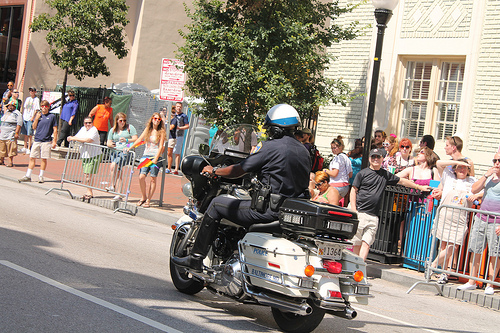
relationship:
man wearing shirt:
[86, 96, 113, 149] [93, 104, 112, 132]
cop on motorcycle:
[169, 103, 311, 272] [162, 117, 369, 329]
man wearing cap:
[341, 147, 433, 289] [370, 149, 384, 156]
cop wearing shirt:
[169, 103, 311, 272] [332, 150, 409, 214]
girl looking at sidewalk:
[320, 133, 356, 209] [1, 142, 498, 306]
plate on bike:
[314, 242, 345, 259] [175, 154, 361, 323]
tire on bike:
[168, 227, 206, 295] [168, 120, 371, 331]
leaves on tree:
[179, 3, 365, 108] [181, 0, 367, 151]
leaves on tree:
[79, 38, 84, 41] [169, 1, 373, 187]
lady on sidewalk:
[432, 160, 471, 279] [367, 259, 498, 308]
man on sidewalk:
[341, 147, 431, 280] [1, 142, 498, 306]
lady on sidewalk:
[432, 160, 471, 279] [1, 142, 498, 306]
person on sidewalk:
[471, 151, 496, 296] [1, 142, 498, 306]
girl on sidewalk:
[121, 112, 167, 208] [1, 142, 498, 306]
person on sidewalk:
[157, 90, 190, 175] [1, 142, 498, 306]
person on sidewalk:
[388, 134, 414, 171] [1, 142, 498, 306]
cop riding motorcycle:
[96, 78, 338, 242] [176, 145, 417, 312]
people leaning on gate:
[64, 100, 218, 213] [68, 144, 135, 201]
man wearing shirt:
[86, 96, 113, 149] [95, 105, 110, 128]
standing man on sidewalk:
[18, 98, 56, 193] [2, 144, 229, 222]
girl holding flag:
[97, 82, 182, 238] [136, 143, 178, 195]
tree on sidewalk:
[181, 0, 367, 151] [21, 135, 188, 223]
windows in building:
[411, 51, 495, 139] [313, 1, 483, 177]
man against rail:
[341, 147, 431, 280] [368, 175, 484, 286]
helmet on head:
[260, 104, 310, 140] [255, 99, 307, 147]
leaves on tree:
[207, 16, 269, 63] [176, 2, 341, 134]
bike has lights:
[170, 144, 368, 333] [297, 253, 381, 285]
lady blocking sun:
[432, 160, 471, 275] [14, 18, 488, 195]